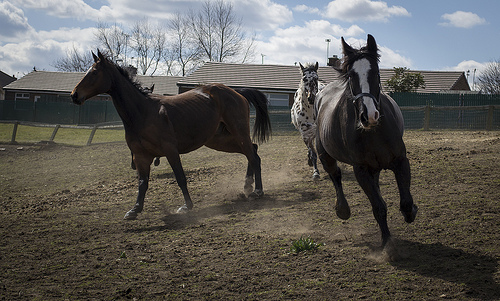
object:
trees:
[182, 0, 258, 65]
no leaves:
[47, 0, 261, 77]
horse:
[308, 34, 418, 262]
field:
[0, 120, 499, 300]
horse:
[69, 48, 273, 220]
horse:
[291, 62, 326, 180]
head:
[335, 34, 382, 133]